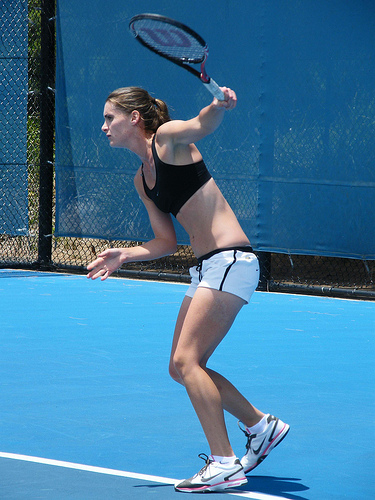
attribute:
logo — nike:
[197, 471, 222, 483]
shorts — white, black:
[182, 242, 261, 306]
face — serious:
[99, 107, 121, 148]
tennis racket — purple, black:
[125, 13, 223, 100]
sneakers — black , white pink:
[178, 413, 291, 492]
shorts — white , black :
[176, 244, 259, 301]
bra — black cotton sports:
[135, 136, 216, 219]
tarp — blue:
[4, 4, 363, 256]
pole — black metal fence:
[37, 8, 62, 266]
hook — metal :
[25, 83, 53, 96]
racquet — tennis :
[130, 8, 243, 112]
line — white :
[5, 447, 293, 498]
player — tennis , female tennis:
[79, 1, 299, 491]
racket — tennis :
[121, 6, 242, 108]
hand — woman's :
[212, 81, 240, 110]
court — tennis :
[2, 270, 361, 488]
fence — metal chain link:
[4, 8, 361, 295]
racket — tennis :
[129, 9, 245, 115]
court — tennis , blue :
[4, 6, 359, 490]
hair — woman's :
[110, 80, 182, 125]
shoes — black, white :
[174, 412, 288, 494]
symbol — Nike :
[217, 455, 230, 464]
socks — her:
[202, 414, 272, 461]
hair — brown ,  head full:
[106, 81, 172, 125]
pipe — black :
[36, 5, 51, 269]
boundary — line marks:
[3, 448, 255, 498]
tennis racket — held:
[121, 15, 238, 112]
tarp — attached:
[79, 29, 374, 241]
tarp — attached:
[213, 74, 370, 245]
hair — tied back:
[121, 83, 200, 138]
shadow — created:
[204, 464, 294, 498]